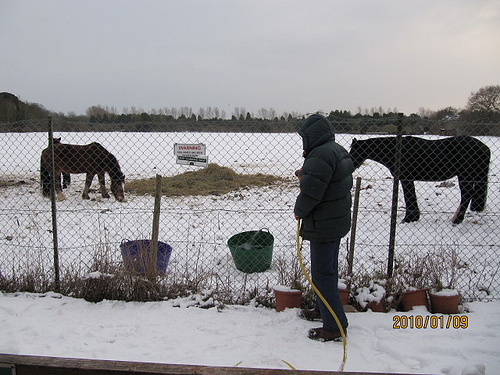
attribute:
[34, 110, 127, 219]
horse — brown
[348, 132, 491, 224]
horse — black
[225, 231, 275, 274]
bucket — green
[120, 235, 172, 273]
bucket — blue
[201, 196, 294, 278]
pail — green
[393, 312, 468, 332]
timestamp — yellow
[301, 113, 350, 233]
jacket — black, puffy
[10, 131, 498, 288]
field — snowy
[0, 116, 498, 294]
wire fence — long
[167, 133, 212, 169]
signs/snow — white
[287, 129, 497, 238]
horse — black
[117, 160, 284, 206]
hay — in a pile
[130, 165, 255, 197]
hay — brown